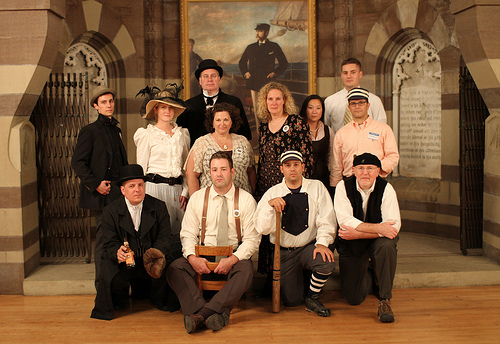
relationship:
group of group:
[72, 58, 400, 335] [71, 58, 402, 334]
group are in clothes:
[71, 58, 402, 334] [72, 91, 400, 328]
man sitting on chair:
[164, 152, 258, 334] [193, 244, 233, 302]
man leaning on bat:
[253, 150, 331, 318] [271, 205, 282, 313]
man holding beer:
[91, 164, 178, 320] [121, 238, 136, 268]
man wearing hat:
[175, 58, 251, 143] [194, 60, 223, 79]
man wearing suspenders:
[164, 152, 258, 334] [200, 187, 241, 247]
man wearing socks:
[253, 150, 331, 318] [307, 269, 330, 298]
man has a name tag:
[328, 89, 402, 186] [367, 131, 378, 139]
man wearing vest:
[335, 155, 402, 327] [339, 174, 385, 223]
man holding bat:
[253, 150, 331, 318] [271, 205, 282, 313]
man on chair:
[164, 152, 258, 334] [193, 244, 233, 302]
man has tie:
[323, 61, 388, 130] [342, 106, 350, 125]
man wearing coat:
[91, 164, 178, 320] [91, 197, 177, 316]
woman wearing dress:
[252, 82, 312, 191] [257, 113, 314, 186]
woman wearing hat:
[133, 90, 189, 232] [141, 90, 185, 118]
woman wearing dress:
[133, 90, 189, 232] [133, 123, 189, 224]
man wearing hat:
[328, 89, 402, 186] [345, 89, 367, 99]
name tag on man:
[367, 131, 378, 139] [328, 89, 402, 186]